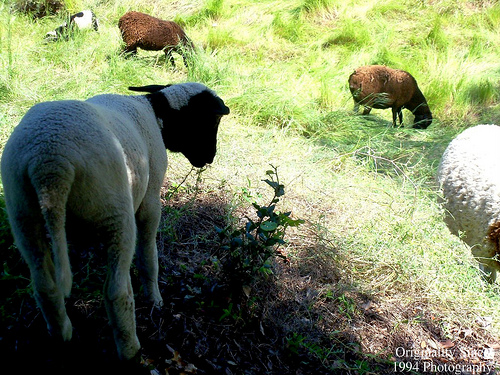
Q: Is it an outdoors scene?
A: Yes, it is outdoors.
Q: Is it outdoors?
A: Yes, it is outdoors.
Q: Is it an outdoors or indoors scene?
A: It is outdoors.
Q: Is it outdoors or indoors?
A: It is outdoors.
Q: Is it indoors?
A: No, it is outdoors.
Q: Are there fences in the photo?
A: No, there are no fences.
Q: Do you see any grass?
A: Yes, there is grass.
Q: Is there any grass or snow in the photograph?
A: Yes, there is grass.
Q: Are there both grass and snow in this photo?
A: No, there is grass but no snow.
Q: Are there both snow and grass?
A: No, there is grass but no snow.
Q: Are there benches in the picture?
A: No, there are no benches.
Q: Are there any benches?
A: No, there are no benches.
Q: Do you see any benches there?
A: No, there are no benches.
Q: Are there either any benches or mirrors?
A: No, there are no benches or mirrors.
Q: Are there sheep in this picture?
A: Yes, there is a sheep.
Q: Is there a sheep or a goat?
A: Yes, there is a sheep.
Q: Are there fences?
A: No, there are no fences.